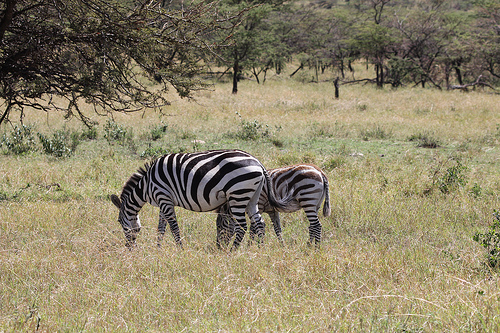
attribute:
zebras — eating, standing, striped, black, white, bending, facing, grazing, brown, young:
[99, 142, 336, 265]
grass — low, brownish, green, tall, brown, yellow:
[1, 88, 498, 332]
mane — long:
[113, 160, 166, 196]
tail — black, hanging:
[263, 173, 334, 218]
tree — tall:
[6, 0, 224, 235]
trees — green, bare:
[142, 4, 498, 109]